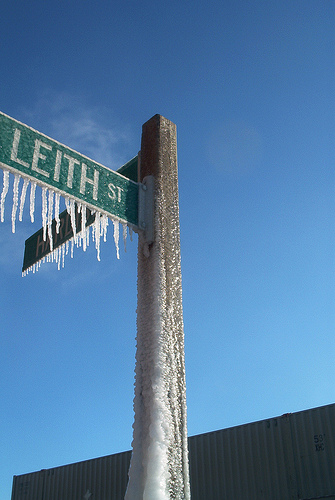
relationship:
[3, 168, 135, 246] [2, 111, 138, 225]
ice on sign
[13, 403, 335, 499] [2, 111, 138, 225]
building by sign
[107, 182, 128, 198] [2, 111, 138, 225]
st on sign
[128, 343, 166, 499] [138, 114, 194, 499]
ice on pole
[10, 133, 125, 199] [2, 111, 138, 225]
leith st on sign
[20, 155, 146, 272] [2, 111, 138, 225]
sign behind sign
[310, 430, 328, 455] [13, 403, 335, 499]
writing on building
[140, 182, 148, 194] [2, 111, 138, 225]
bolts on sign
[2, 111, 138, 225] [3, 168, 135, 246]
sign covered in ice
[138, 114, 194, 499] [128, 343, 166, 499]
pole covered in ice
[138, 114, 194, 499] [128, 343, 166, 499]
pole covered by ice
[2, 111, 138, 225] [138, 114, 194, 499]
sign on a pole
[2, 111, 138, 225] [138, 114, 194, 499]
sign in on pole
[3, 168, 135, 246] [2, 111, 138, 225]
ice hanging on sign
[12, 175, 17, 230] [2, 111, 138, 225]
icicle on sign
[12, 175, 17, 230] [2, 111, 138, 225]
icicle hanging on sign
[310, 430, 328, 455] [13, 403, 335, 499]
writing on side of building